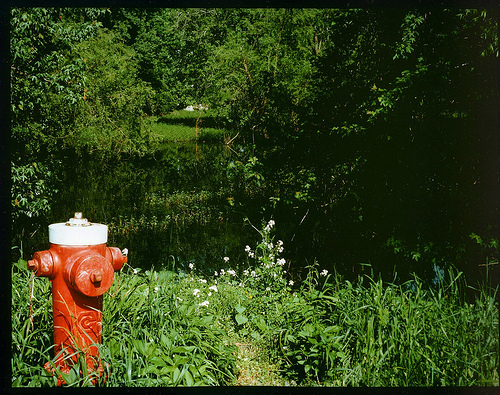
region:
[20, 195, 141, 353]
red hydrant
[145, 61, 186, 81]
green leaves in brown trees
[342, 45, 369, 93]
green leaves in brown trees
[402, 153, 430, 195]
green leaves in brown trees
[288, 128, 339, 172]
green leaves in brown trees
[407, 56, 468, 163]
green leaves in brown trees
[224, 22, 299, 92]
green leaves in brown trees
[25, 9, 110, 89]
green leaves in brown trees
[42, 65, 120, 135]
green leaves in brown trees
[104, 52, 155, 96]
green leaves in brown trees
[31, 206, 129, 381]
red and white fire hydrant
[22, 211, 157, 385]
fire hydrant entrenched in green grass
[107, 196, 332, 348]
Green grass with white flower toppings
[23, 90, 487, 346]
green forestry surrounding body of water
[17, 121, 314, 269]
tree reflections in body of water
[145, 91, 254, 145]
huge shadow cast by tree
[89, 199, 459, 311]
white flowers along the edge of a body of water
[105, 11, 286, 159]
white building shrouded by sea of trees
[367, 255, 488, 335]
blue flowers in a swarm of green grass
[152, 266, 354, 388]
slightly visible brown trail in the midst of all the grass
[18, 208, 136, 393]
red fire hydrant in grass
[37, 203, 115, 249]
white top on red fire hydrant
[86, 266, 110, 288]
lug on red fire hydrant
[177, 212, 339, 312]
white flower in grass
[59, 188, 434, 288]
body of water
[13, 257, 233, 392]
tall grass surrounding red fire hydrant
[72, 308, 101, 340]
letter engraved on side of fire hydrant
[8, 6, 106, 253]
tall tree next to body of water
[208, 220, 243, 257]
light reflecting in surface of water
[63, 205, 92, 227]
lug on top of fire hydrant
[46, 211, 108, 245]
White metal cap on fire hydrant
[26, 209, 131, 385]
Fire hydrant in grass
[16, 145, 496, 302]
Pond in park area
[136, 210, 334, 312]
Wild flowers growing in grassy area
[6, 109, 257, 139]
Shoreline opposite of pond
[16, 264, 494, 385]
Grass covered ground around fire hydrant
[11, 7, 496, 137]
leaf covered trees on pond shoreline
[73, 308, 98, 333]
Hydrant manufacturer mark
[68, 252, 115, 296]
Fire hose attachment cover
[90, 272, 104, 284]
Square bolt to release nozzle attachment cover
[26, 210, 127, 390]
The red fire hydrant in the grass.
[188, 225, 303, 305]
The patch of white flowers.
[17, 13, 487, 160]
The array of green trees.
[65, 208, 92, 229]
Bolt on top of the fire hydrant.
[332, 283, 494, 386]
The patch of grass on the right.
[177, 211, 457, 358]
Flowers in the grassy field.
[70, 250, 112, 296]
Bolt on the front of the hydrant.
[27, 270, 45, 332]
Chain hanging from the hydrant.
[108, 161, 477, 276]
Small still body of water.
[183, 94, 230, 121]
White flowers.